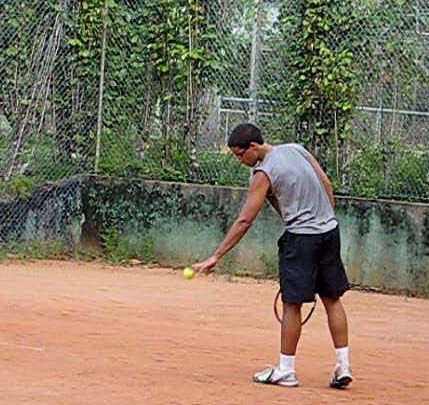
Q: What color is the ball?
A: Yellow.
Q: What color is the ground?
A: Red.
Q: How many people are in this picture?
A: One.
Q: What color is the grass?
A: Green.